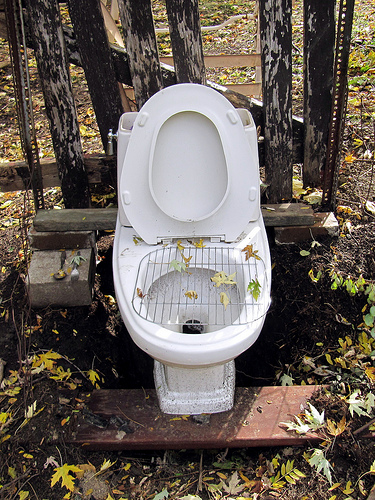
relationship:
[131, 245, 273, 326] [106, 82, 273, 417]
grill grate over toilet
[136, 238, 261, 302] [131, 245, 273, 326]
leaves on top of grill grate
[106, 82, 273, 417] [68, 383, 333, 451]
toilet sitting on wood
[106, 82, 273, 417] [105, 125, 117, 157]
toilet has handle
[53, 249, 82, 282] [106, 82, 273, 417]
silverware by toilet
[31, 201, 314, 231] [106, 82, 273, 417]
wood behind toilet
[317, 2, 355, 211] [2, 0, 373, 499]
rod going into ground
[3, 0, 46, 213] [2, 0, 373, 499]
rod into ground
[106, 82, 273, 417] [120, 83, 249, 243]
toilet has seat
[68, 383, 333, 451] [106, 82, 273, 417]
wood under toilet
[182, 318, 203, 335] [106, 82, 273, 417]
hole inside toilet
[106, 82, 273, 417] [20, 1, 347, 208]
toilet in woods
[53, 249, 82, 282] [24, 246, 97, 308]
silverware sitting on block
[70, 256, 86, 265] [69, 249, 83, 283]
leaf laying on fork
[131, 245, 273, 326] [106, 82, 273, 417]
grill grate on top of toilet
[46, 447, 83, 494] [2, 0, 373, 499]
leaf on ground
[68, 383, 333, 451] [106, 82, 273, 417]
wood underneath toilet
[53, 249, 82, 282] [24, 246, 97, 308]
silverware laying on block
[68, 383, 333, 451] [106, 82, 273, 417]
wood supporting toilet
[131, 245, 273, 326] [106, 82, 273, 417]
grill grate covering toilet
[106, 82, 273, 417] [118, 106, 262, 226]
toilet has tank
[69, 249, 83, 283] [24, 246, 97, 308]
fork sitting on block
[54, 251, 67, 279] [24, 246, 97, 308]
silverware sitting on block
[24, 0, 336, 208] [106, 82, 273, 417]
trunks behind toilet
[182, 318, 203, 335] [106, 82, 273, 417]
hole in toilet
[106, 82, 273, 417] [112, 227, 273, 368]
toilet has bowl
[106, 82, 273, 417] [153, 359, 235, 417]
toilet has base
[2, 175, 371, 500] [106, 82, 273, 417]
leaves near by toilet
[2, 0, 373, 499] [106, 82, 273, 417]
ground behind toilet